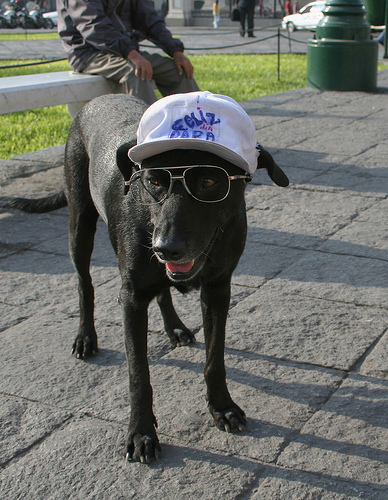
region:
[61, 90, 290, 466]
Black dog wearing glasses and a cap.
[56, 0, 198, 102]
Man sitting on bench with hands on knees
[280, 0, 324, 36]
White car on the road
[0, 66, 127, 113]
White bench in front of the grass.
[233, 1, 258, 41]
Person crossing the street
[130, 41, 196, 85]
Hands on man's knees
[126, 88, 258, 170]
White cap on dog's head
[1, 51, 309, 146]
Grassy area next to sidewalk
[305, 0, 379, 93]
Green base at the end of the sidewalk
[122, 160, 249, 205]
Silver-framed glasses on a dog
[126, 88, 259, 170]
dog's white baseball hat with a blue logo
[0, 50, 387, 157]
the larger patch of grass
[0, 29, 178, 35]
smaller patch of grass in the background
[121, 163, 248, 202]
dog's silver glasses frame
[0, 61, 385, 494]
pavement stone sidewalk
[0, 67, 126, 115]
white marble bench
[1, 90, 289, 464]
black Labrador retriever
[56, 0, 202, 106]
man sitting on the bench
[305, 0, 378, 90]
green streetlight base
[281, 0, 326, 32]
white sedan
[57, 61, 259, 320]
the dog is black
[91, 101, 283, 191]
dog is wearing a cap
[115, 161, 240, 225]
dog is wearing eyeglasses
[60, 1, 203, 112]
a man sitting on the bench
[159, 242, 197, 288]
the tongue is pink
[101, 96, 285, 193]
the cap is white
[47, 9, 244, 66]
man is wearing a jacket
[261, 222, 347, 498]
the floor is made of concrete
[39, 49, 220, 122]
the bench is white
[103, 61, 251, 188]
dog wearing a hat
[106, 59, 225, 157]
the hat is white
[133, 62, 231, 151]
blue letters on hat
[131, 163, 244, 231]
dog is wearing glasses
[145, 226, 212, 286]
dog's mouth is open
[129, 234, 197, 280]
dog's tongue is pink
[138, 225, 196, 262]
dog's nose is black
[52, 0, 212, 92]
man sitting on bench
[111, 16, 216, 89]
man's hands on knee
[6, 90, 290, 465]
Black dog has mouth opened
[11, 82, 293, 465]
Black dog wearing white hat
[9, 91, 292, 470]
Black dog wearing sunglasses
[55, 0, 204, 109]
Person sitting on bench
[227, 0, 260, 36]
Person carrying briefcase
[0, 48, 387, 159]
Green grass behind bench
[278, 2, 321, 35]
White car is parked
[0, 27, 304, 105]
Rope behind green post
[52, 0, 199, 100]
Person wearing blue jacket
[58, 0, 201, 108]
Person wearing brown pants